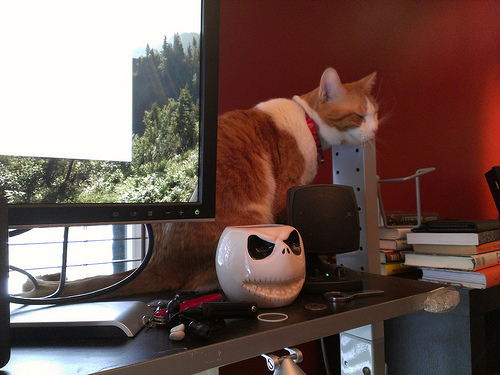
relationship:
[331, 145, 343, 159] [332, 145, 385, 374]
hole in pole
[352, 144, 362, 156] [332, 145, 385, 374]
hole in pole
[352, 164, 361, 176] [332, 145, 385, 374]
hole in pole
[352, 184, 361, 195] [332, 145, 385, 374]
hole in pole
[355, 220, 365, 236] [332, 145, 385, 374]
hole in pole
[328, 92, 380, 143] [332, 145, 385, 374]
cat face on pole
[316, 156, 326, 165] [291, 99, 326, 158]
bell on collar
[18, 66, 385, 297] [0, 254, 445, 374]
cat sitting on table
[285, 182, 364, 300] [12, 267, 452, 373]
speaker sitting on desk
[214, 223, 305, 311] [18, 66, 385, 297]
bowl next to cat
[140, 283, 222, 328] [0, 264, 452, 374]
knife on desk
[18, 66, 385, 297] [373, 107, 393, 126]
cat has whiskers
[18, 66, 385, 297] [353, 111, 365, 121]
cat has eye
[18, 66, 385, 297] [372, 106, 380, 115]
cat has eye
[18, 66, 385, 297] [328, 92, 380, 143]
cat has cat face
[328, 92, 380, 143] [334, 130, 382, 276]
cat face rubbing on post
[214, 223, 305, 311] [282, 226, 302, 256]
bowl has eye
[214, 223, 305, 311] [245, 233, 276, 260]
bowl has eye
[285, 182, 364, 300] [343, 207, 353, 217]
speaker has knob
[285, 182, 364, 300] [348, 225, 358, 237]
speaker has knob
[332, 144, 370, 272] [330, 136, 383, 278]
holes in post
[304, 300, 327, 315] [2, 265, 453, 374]
quarter lying on shelf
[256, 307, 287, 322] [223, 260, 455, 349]
hair band on table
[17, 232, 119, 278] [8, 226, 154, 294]
light streaming through window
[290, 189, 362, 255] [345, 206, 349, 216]
speaker with light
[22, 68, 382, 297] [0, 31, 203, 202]
cat sitting next to scene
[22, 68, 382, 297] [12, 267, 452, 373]
cat sitting on desk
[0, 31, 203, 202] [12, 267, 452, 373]
scene on desk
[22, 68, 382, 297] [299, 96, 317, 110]
cat rubbing cat neck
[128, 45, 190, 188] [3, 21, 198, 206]
scene on screen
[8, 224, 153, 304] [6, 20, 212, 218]
window under monitor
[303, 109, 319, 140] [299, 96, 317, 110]
collar around cat neck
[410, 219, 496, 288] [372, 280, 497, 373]
books on table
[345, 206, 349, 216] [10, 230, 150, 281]
light coming through window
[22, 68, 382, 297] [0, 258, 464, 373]
cat on desk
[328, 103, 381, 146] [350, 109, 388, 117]
cat face with eyes